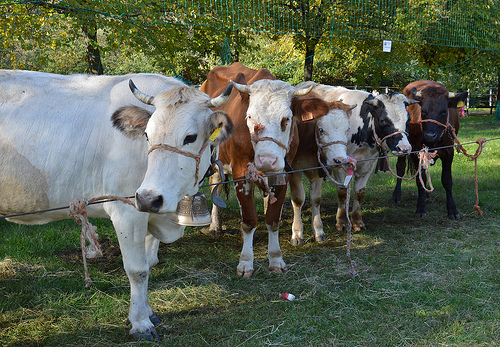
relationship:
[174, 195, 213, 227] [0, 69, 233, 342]
bell on cattle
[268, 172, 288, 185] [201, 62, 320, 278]
bell on cow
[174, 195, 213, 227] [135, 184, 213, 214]
bell under chin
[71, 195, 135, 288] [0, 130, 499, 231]
rope tied wire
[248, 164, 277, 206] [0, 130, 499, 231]
rope tied to wire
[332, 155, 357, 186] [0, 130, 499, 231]
rope tied to wire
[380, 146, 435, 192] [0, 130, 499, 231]
rope tied to wire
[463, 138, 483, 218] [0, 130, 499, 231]
rope tied to wire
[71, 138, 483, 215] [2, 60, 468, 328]
rope on cattle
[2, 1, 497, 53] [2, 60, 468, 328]
fince in front of cows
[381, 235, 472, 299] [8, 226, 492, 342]
hay on top of grass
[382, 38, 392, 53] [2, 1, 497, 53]
sign on fence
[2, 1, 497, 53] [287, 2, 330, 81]
fence in front of tree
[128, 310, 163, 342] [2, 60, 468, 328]
hove of cattle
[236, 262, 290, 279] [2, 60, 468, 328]
hove of cattle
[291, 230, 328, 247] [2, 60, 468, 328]
hove of cattle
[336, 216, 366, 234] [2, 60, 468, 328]
hove of cattle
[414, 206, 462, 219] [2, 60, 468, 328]
hove of cattle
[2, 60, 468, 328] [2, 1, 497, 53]
cows behind fence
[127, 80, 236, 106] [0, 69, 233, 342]
horns on cattle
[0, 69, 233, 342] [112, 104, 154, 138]
cattle has ear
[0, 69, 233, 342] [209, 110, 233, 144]
cattle has ear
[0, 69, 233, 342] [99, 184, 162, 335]
cattle has leg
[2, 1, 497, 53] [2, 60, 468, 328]
fence over cows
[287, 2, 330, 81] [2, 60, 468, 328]
tree behind cows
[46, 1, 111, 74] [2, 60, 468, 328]
tree behind cows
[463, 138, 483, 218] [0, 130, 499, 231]
rope on fence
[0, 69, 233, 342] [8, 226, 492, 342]
cattle on grass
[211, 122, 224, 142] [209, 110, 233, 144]
tag on ear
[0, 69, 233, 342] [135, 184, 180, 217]
cattle has nose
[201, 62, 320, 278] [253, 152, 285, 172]
cow has nose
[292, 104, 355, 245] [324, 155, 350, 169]
cow has nose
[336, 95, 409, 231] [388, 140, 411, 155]
cow has nose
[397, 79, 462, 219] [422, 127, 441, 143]
cow has nose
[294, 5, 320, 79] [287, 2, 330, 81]
part of tree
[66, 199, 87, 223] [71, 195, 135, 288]
knot on rope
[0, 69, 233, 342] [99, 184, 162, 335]
cattle has front leg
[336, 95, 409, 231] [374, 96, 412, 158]
cow has head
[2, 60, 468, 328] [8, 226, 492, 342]
cows on grass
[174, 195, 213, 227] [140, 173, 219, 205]
bell on neck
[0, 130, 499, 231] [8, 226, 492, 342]
cable above ground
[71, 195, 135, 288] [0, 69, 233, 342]
rope on cattle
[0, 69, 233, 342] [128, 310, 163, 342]
cattle has hove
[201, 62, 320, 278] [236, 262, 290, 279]
cow has hove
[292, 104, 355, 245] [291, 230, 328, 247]
cow has hove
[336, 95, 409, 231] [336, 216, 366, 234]
cow has hove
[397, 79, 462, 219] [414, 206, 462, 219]
cow has hove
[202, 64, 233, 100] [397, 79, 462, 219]
fur on cow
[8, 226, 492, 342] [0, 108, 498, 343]
grass covering ground